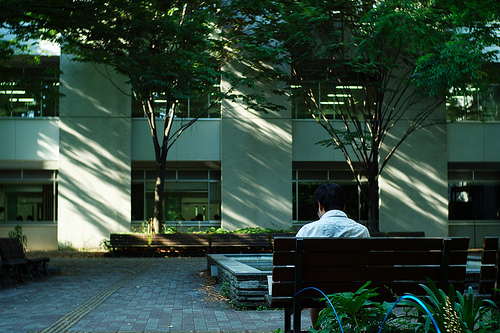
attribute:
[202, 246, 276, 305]
wall — slate topped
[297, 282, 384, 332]
plant — peek over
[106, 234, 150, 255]
bench — far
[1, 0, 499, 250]
building — white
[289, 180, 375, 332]
person — sitting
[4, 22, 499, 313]
building — white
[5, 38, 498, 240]
building — white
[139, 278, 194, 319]
brick — layout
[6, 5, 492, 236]
trees — alongside, creating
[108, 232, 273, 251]
benches — lined, empty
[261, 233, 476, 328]
bench — wooden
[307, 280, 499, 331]
plants — green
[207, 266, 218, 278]
box — electric mounted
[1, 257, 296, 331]
pavement — brick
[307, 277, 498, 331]
tropical plants — foreground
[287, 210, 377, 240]
t-shirt — white